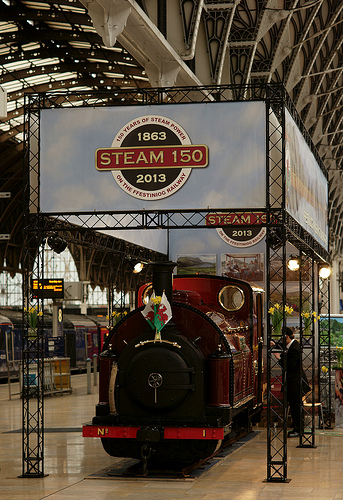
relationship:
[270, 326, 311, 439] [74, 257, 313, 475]
man standing next to a train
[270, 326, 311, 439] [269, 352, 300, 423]
man wearing a black shirt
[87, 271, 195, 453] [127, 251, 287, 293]
smokestack on a red train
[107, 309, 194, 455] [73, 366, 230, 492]
flowers above man wearing black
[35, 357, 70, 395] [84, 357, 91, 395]
cart next to pole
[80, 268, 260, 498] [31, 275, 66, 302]
train above sign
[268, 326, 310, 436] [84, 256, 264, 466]
man in black near train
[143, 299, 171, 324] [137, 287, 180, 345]
dragons on flags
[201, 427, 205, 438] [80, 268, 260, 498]
i on train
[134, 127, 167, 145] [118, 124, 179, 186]
1863 on background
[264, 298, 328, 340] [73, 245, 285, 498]
flowers on side of train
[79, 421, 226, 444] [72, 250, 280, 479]
stripe on train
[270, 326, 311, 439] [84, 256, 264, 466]
man next to train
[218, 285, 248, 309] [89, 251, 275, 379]
window on train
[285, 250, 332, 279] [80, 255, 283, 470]
lights behind train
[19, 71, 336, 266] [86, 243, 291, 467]
canopy above steam engine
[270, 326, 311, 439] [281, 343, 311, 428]
man wearing suit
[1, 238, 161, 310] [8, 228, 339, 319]
window along wall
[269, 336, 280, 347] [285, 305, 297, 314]
flower pot with flower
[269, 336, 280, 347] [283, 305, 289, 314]
flower pot with flower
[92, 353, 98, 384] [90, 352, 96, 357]
metal pole with blue top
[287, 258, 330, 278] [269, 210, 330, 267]
lights attached to beams